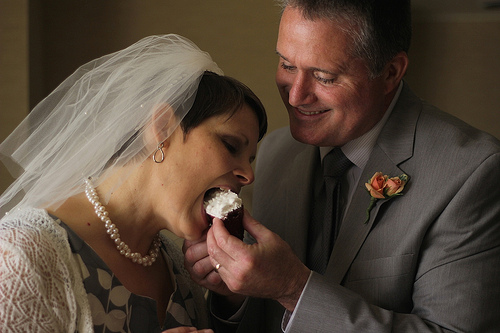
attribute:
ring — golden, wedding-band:
[214, 260, 221, 271]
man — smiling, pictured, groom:
[183, 3, 500, 332]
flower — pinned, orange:
[364, 171, 409, 226]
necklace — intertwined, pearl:
[84, 179, 163, 266]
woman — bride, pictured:
[1, 70, 268, 333]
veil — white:
[1, 34, 224, 228]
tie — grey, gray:
[307, 146, 354, 275]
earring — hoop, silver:
[152, 145, 165, 163]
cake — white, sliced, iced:
[203, 186, 244, 242]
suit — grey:
[206, 82, 499, 333]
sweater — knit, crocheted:
[1, 205, 98, 333]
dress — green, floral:
[54, 215, 198, 332]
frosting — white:
[205, 188, 243, 217]